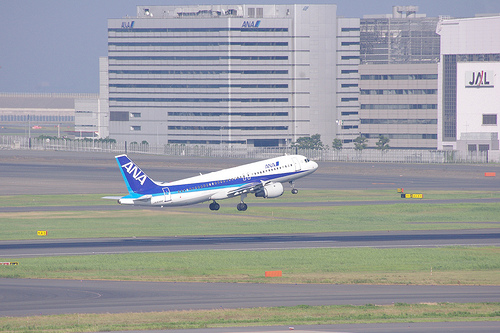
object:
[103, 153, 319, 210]
airplane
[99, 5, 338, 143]
building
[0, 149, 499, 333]
airport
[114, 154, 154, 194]
tail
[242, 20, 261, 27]
name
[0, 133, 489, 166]
fence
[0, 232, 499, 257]
runway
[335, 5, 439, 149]
buildings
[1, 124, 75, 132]
road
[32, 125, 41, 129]
cars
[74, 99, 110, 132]
building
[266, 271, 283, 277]
symbol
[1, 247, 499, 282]
grass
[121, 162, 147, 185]
ana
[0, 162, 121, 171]
shadow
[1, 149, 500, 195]
street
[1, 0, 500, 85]
sky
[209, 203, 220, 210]
gear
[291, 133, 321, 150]
trees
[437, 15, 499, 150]
building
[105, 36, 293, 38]
level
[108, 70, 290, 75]
level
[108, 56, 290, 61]
level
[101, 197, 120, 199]
wing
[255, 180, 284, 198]
engine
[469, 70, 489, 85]
lettering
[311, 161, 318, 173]
nose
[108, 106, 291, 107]
floor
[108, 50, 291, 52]
floor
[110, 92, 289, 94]
floor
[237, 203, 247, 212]
wheel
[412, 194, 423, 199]
object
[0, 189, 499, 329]
field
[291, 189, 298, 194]
wheel